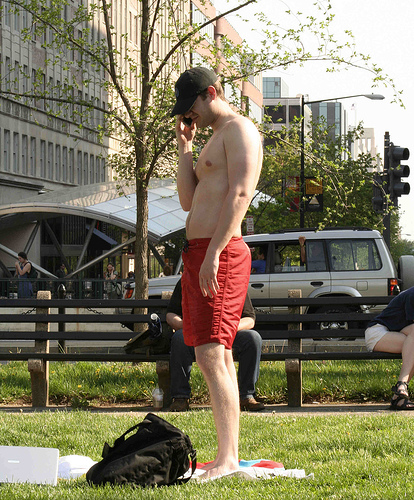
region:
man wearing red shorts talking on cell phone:
[148, 55, 272, 481]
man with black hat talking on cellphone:
[161, 57, 259, 219]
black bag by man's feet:
[88, 410, 195, 494]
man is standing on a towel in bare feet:
[158, 451, 320, 483]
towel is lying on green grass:
[177, 422, 402, 488]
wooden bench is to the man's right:
[5, 282, 149, 383]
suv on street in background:
[128, 211, 384, 325]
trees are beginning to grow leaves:
[10, 12, 387, 234]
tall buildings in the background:
[232, 47, 368, 188]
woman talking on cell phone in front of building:
[97, 257, 124, 300]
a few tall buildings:
[236, 42, 409, 215]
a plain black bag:
[79, 406, 199, 489]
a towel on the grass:
[48, 450, 326, 493]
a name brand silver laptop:
[0, 438, 67, 491]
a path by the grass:
[28, 390, 411, 463]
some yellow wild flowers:
[88, 362, 151, 398]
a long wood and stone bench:
[7, 276, 398, 408]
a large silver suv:
[114, 228, 406, 351]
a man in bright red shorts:
[148, 56, 268, 480]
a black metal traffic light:
[366, 127, 409, 245]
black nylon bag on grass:
[83, 411, 198, 485]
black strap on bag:
[175, 435, 196, 484]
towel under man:
[187, 455, 315, 486]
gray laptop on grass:
[1, 444, 58, 485]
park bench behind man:
[3, 288, 409, 412]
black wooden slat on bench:
[0, 296, 394, 309]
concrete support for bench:
[282, 287, 305, 404]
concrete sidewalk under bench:
[1, 397, 412, 412]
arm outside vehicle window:
[297, 234, 308, 262]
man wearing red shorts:
[180, 238, 249, 348]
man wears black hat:
[155, 63, 211, 128]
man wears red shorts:
[170, 210, 259, 357]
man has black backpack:
[89, 411, 188, 496]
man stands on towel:
[202, 447, 317, 497]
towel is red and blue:
[163, 443, 299, 487]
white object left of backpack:
[1, 435, 91, 492]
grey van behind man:
[101, 223, 400, 315]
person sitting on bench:
[359, 272, 412, 358]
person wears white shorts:
[346, 314, 410, 358]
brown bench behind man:
[1, 274, 205, 372]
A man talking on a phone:
[110, 46, 274, 496]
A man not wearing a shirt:
[132, 28, 270, 498]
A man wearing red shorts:
[154, 55, 297, 497]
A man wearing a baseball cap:
[151, 61, 244, 144]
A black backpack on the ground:
[85, 378, 212, 498]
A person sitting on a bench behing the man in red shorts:
[136, 213, 298, 414]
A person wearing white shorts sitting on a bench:
[361, 270, 411, 404]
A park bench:
[22, 279, 406, 402]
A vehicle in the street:
[128, 214, 400, 352]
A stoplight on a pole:
[373, 124, 412, 234]